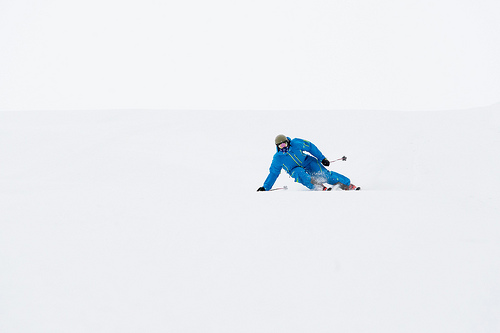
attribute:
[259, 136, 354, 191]
jacket — blue, bright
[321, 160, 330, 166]
glove — black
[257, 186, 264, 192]
glove — black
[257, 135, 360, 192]
skier — traveling, leaning, skiing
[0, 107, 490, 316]
slope — white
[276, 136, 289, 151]
helmet — green, gray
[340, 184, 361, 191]
skates — orange, red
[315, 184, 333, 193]
skates — orange, red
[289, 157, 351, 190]
pants — blue, bright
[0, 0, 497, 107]
sky — bright, gray